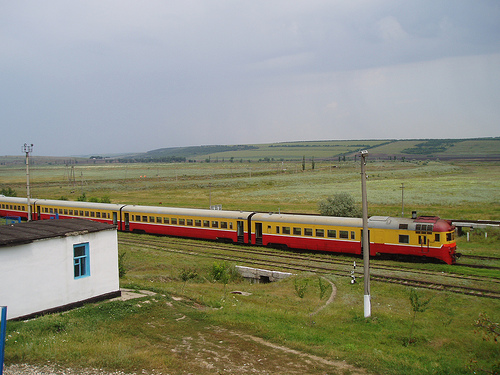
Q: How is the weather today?
A: It is cloudy.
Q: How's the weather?
A: It is cloudy.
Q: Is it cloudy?
A: Yes, it is cloudy.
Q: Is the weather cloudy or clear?
A: It is cloudy.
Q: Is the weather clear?
A: No, it is cloudy.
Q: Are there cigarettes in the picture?
A: No, there are no cigarettes.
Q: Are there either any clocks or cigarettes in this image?
A: No, there are no cigarettes or clocks.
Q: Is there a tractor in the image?
A: No, there are no tractors.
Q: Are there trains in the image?
A: Yes, there is a train.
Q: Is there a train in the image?
A: Yes, there is a train.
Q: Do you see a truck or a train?
A: Yes, there is a train.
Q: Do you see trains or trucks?
A: Yes, there is a train.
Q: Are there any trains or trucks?
A: Yes, there is a train.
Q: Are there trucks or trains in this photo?
A: Yes, there is a train.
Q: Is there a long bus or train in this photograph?
A: Yes, there is a long train.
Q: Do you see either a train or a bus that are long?
A: Yes, the train is long.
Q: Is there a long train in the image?
A: Yes, there is a long train.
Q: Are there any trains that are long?
A: Yes, there is a train that is long.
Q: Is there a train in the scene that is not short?
A: Yes, there is a long train.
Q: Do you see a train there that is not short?
A: Yes, there is a long train.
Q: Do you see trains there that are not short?
A: Yes, there is a long train.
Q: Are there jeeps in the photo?
A: No, there are no jeeps.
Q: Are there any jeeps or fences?
A: No, there are no jeeps or fences.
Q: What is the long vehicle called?
A: The vehicle is a train.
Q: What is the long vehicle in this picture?
A: The vehicle is a train.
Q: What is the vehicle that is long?
A: The vehicle is a train.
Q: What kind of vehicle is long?
A: The vehicle is a train.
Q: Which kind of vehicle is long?
A: The vehicle is a train.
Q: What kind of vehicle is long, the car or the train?
A: The train is long.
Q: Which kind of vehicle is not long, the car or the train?
A: The car is not long.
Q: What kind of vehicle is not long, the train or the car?
A: The car is not long.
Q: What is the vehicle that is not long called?
A: The vehicle is a car.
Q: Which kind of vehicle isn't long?
A: The vehicle is a car.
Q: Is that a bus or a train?
A: That is a train.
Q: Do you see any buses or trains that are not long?
A: No, there is a train but it is long.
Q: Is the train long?
A: Yes, the train is long.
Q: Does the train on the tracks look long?
A: Yes, the train is long.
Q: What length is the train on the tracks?
A: The train is long.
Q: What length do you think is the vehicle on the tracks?
A: The train is long.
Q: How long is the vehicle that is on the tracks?
A: The train is long.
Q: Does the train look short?
A: No, the train is long.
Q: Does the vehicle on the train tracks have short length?
A: No, the train is long.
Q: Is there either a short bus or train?
A: No, there is a train but it is long.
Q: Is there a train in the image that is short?
A: No, there is a train but it is long.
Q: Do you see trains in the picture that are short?
A: No, there is a train but it is long.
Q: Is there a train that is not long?
A: No, there is a train but it is long.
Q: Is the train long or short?
A: The train is long.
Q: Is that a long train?
A: Yes, that is a long train.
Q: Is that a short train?
A: No, that is a long train.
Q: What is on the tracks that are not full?
A: The train is on the tracks.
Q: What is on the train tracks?
A: The train is on the tracks.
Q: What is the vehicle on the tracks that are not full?
A: The vehicle is a train.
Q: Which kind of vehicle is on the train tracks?
A: The vehicle is a train.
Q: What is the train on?
A: The train is on the train tracks.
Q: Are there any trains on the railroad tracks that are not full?
A: Yes, there is a train on the train tracks.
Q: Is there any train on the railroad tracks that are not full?
A: Yes, there is a train on the train tracks.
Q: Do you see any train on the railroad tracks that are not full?
A: Yes, there is a train on the train tracks.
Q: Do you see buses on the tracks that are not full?
A: No, there is a train on the train tracks.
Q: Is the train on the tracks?
A: Yes, the train is on the tracks.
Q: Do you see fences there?
A: No, there are no fences.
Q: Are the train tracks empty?
A: Yes, the train tracks are empty.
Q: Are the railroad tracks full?
A: No, the railroad tracks are empty.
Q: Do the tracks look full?
A: No, the tracks are empty.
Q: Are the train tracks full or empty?
A: The train tracks are empty.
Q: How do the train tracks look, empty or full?
A: The train tracks are empty.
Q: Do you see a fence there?
A: No, there are no fences.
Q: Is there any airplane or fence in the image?
A: No, there are no fences or airplanes.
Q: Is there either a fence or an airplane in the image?
A: No, there are no fences or airplanes.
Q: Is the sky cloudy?
A: Yes, the sky is cloudy.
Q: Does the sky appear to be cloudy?
A: Yes, the sky is cloudy.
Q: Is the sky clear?
A: No, the sky is cloudy.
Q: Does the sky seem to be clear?
A: No, the sky is cloudy.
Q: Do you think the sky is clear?
A: No, the sky is cloudy.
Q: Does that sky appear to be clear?
A: No, the sky is cloudy.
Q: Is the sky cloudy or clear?
A: The sky is cloudy.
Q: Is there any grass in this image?
A: Yes, there is grass.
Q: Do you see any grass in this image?
A: Yes, there is grass.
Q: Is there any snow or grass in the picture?
A: Yes, there is grass.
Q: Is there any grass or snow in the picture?
A: Yes, there is grass.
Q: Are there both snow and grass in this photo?
A: No, there is grass but no snow.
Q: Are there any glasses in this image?
A: No, there are no glasses.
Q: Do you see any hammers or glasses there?
A: No, there are no glasses or hammers.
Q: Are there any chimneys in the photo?
A: No, there are no chimneys.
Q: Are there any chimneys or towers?
A: No, there are no chimneys or towers.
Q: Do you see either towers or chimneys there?
A: No, there are no chimneys or towers.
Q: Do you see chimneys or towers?
A: No, there are no chimneys or towers.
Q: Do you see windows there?
A: Yes, there is a window.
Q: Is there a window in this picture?
A: Yes, there is a window.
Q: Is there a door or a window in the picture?
A: Yes, there is a window.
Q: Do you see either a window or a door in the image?
A: Yes, there is a window.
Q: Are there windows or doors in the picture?
A: Yes, there is a window.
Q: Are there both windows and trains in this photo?
A: Yes, there are both a window and a train.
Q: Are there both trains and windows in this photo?
A: Yes, there are both a window and a train.